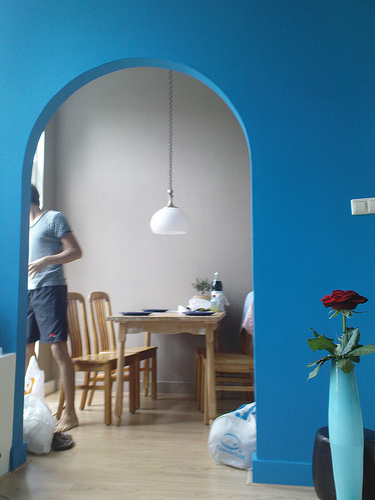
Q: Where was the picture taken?
A: A house.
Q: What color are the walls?
A: Blue.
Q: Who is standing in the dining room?
A: A man.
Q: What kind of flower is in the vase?
A: A rose.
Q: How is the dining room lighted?
A: With a hanging lamp.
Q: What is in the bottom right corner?
A: A rose in a vase.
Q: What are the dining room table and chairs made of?
A: Wood.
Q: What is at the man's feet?
A: A plastic bag.